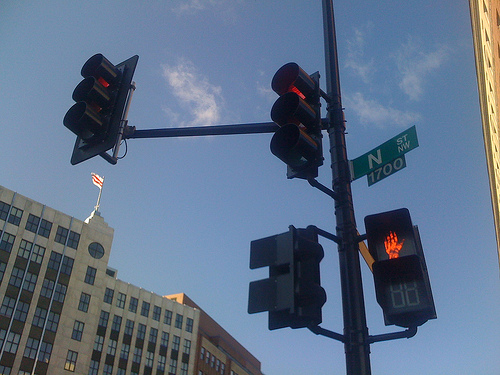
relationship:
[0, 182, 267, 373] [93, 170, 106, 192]
building has flag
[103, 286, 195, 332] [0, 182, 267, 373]
windows on building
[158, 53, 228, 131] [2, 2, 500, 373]
cloud in sky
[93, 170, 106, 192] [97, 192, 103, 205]
flag on pole